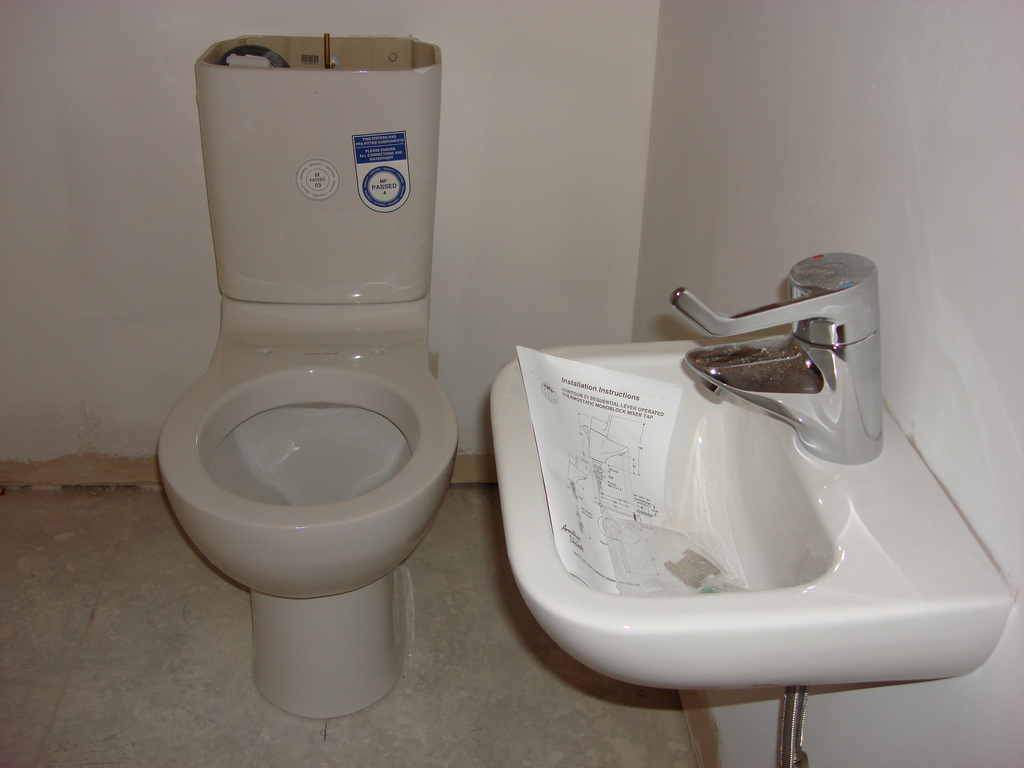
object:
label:
[351, 130, 412, 215]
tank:
[194, 34, 443, 306]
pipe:
[777, 686, 809, 768]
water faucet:
[670, 253, 883, 466]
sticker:
[293, 157, 343, 201]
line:
[28, 483, 140, 767]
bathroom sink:
[490, 334, 1018, 692]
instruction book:
[517, 344, 686, 596]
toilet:
[158, 33, 460, 719]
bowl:
[159, 366, 458, 529]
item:
[663, 549, 721, 589]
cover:
[602, 516, 752, 598]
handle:
[670, 253, 880, 348]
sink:
[490, 253, 1015, 690]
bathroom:
[0, 0, 1022, 764]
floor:
[0, 483, 703, 767]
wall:
[5, 0, 658, 490]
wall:
[632, 0, 1024, 768]